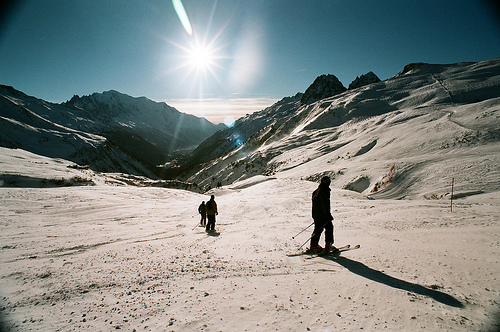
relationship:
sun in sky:
[175, 25, 217, 82] [3, 3, 498, 127]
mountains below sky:
[0, 58, 499, 331] [3, 3, 498, 127]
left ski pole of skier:
[286, 217, 315, 240] [308, 174, 339, 256]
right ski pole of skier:
[300, 227, 328, 258] [308, 174, 339, 256]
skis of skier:
[289, 238, 363, 263] [308, 174, 339, 256]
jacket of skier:
[311, 188, 331, 222] [308, 174, 339, 256]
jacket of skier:
[205, 202, 217, 215] [205, 197, 222, 233]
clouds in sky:
[179, 91, 276, 131] [3, 3, 498, 127]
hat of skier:
[321, 173, 331, 182] [308, 174, 339, 256]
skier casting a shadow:
[308, 174, 339, 256] [326, 251, 462, 310]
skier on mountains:
[308, 174, 339, 256] [0, 58, 499, 331]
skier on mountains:
[205, 197, 222, 233] [0, 58, 499, 331]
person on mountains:
[198, 197, 207, 226] [0, 58, 499, 331]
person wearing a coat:
[198, 197, 207, 226] [199, 208, 207, 215]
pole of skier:
[192, 218, 208, 235] [205, 197, 222, 233]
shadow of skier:
[326, 251, 462, 310] [308, 174, 339, 256]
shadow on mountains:
[326, 251, 462, 310] [0, 58, 499, 331]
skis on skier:
[289, 238, 363, 263] [308, 174, 339, 256]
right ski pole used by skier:
[300, 227, 328, 258] [308, 174, 339, 256]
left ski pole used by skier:
[286, 217, 315, 240] [308, 174, 339, 256]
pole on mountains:
[192, 218, 208, 235] [0, 58, 499, 331]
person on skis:
[198, 197, 207, 226] [199, 221, 207, 228]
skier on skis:
[308, 174, 339, 256] [289, 238, 363, 263]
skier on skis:
[205, 197, 222, 233] [197, 227, 218, 235]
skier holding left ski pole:
[308, 174, 339, 256] [286, 217, 315, 240]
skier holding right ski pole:
[308, 174, 339, 256] [300, 227, 328, 258]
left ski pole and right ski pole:
[286, 217, 315, 240] [300, 227, 328, 258]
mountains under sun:
[0, 58, 499, 331] [175, 25, 217, 82]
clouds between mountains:
[179, 91, 276, 131] [0, 58, 499, 331]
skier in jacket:
[308, 174, 339, 256] [311, 188, 331, 222]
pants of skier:
[310, 220, 334, 245] [308, 174, 339, 256]